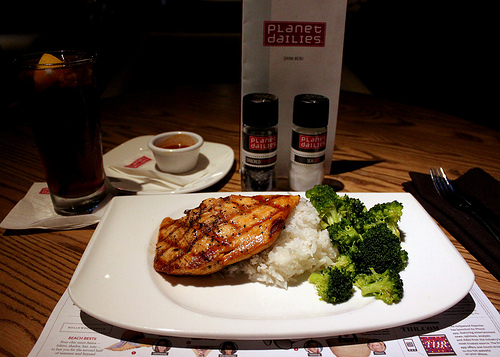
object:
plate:
[66, 193, 476, 338]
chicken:
[153, 194, 300, 278]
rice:
[223, 192, 338, 288]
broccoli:
[301, 183, 408, 306]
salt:
[290, 93, 331, 191]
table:
[0, 90, 499, 354]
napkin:
[401, 166, 500, 284]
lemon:
[37, 53, 65, 71]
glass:
[17, 51, 114, 216]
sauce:
[148, 132, 205, 173]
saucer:
[101, 132, 236, 194]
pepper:
[240, 92, 279, 196]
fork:
[429, 167, 500, 236]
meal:
[155, 185, 408, 308]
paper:
[26, 281, 499, 356]